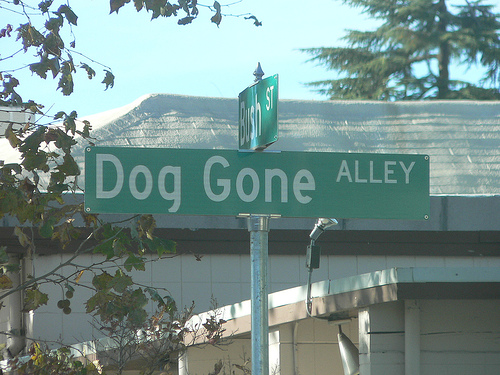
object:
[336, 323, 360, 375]
lamp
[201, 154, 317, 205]
gone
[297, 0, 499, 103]
evergreen tree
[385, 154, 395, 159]
ground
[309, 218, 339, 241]
lights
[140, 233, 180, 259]
leaf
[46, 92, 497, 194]
building roof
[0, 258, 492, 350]
wall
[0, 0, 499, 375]
outside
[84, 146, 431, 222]
sign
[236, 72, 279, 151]
sign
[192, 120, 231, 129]
shingles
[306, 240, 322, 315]
conduit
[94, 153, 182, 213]
word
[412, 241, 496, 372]
corner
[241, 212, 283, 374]
pole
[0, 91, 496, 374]
building